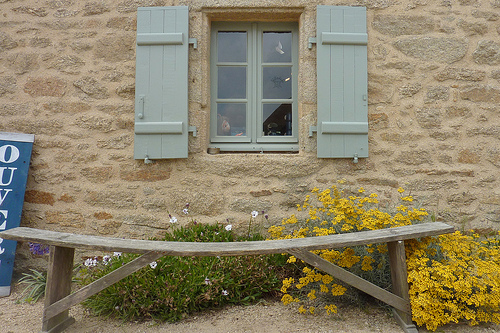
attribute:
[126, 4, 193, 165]
shutter — gray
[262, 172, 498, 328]
bushes — yellow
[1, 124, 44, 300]
sign — blue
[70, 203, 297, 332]
bush — green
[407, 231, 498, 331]
flowers — yellow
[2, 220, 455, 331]
bench — long, wooden, gray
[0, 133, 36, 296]
sign — blue, white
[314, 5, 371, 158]
shutters — gray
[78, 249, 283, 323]
flower — purple, white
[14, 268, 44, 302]
grass — long, leafy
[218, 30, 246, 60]
pane — glass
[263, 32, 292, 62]
pane — glass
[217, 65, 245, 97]
pane — glass